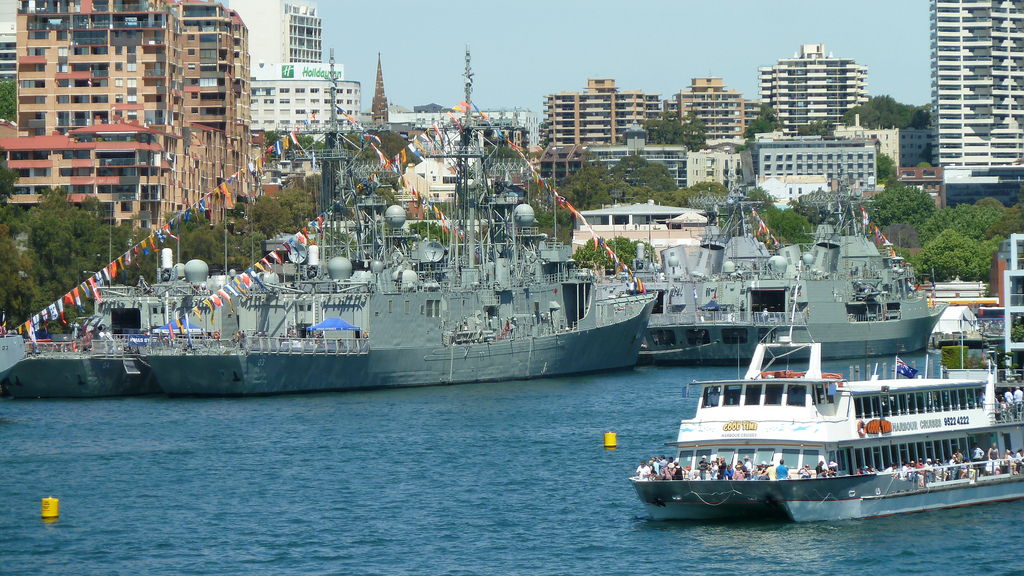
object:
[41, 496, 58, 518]
item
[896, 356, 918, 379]
flag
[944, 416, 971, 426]
letter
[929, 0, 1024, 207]
building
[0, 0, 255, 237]
building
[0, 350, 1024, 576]
water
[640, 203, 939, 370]
ship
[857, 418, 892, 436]
logo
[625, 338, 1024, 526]
boat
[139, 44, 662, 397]
ship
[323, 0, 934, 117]
blue sky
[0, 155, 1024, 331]
land